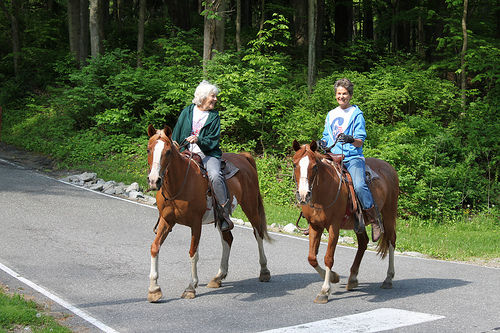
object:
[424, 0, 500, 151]
tree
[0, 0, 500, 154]
wooded area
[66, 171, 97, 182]
stone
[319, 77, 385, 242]
person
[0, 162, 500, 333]
ground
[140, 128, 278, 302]
chestnut horse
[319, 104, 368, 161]
jacket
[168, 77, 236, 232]
woman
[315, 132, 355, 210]
reigns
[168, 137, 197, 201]
reigns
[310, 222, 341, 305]
leg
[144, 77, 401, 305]
women horses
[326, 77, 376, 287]
woman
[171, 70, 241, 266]
woman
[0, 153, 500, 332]
road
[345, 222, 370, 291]
leg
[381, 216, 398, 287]
leg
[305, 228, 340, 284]
leg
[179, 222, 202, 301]
leg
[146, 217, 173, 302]
leg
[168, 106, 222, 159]
cardigan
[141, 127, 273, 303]
horse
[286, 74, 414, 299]
woman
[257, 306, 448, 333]
white marker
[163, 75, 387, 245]
two women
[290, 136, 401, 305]
horse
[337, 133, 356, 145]
gloves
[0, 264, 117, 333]
line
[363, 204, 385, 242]
boot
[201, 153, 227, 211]
pants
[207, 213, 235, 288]
leg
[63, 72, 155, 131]
bushes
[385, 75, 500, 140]
bushes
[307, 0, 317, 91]
trees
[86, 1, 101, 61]
trees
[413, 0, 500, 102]
shrubs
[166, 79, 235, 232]
lady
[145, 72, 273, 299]
woman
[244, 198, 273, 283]
leg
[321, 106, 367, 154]
shirt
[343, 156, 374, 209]
pants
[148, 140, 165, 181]
blaze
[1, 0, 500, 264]
forest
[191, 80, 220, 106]
hair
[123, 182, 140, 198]
rocks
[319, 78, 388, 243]
woman